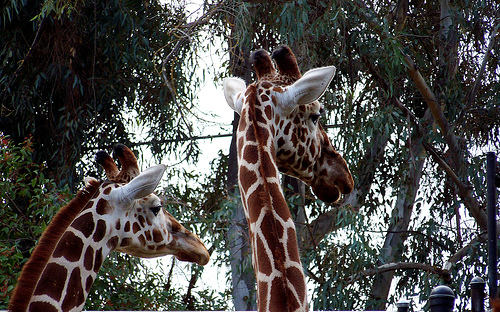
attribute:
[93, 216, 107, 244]
spot — brown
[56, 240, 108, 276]
spot — brown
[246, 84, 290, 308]
mane — brown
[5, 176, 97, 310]
mane — brown, short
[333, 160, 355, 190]
giraffe nose — brown, white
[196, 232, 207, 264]
giraffe nose — brown, white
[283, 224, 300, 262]
spot — brown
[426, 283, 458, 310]
post — black, metal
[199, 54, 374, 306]
giraffe — outdoors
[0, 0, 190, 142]
trees — thick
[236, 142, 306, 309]
neck — long 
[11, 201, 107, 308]
neck — long 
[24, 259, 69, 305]
spot — brown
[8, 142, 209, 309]
giraffe — white, brown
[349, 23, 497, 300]
tree — brown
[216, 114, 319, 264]
mane — long, black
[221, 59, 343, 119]
giraffe's ears — white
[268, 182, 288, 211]
spot — brown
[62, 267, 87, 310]
spot — brown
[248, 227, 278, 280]
spot — brown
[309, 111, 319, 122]
eye — black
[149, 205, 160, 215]
eye — black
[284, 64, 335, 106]
ear — white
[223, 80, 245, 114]
ear — white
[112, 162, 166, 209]
ear — white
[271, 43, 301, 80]
horn — black tipped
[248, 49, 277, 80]
horn — black tipped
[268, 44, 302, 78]
horn — brown, black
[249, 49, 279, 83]
horn — brown, black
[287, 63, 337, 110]
ear — white tipped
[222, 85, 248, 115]
ear — white tipped